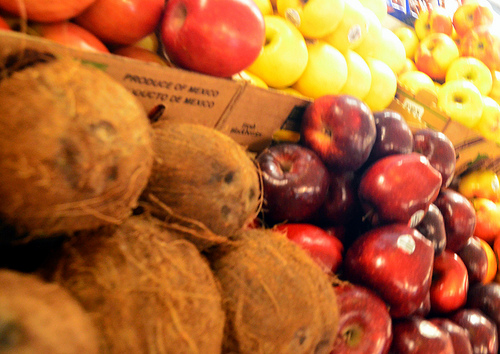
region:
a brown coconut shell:
[18, 65, 168, 240]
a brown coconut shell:
[147, 128, 261, 223]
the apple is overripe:
[257, 131, 340, 215]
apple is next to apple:
[252, 143, 330, 222]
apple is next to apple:
[307, 94, 377, 170]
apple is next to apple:
[270, 221, 340, 273]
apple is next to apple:
[311, 277, 387, 347]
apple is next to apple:
[345, 220, 432, 315]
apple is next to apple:
[395, 316, 450, 347]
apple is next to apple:
[429, 246, 468, 313]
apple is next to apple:
[439, 186, 477, 253]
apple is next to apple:
[370, 109, 414, 162]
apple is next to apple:
[415, 125, 454, 188]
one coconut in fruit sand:
[2, 55, 156, 239]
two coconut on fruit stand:
[3, 63, 259, 244]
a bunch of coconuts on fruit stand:
[10, 62, 341, 349]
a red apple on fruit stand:
[291, 93, 377, 168]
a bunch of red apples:
[236, 100, 496, 342]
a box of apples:
[233, 0, 408, 116]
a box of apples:
[0, 5, 265, 125]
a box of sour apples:
[385, 5, 496, 161]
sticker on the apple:
[336, 215, 434, 317]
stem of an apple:
[263, 140, 300, 181]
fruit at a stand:
[22, 7, 452, 296]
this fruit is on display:
[14, 9, 484, 279]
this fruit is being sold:
[191, 2, 491, 347]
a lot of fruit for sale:
[29, 7, 496, 236]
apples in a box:
[10, 5, 240, 85]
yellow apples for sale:
[266, 4, 405, 96]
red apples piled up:
[290, 119, 490, 336]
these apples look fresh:
[222, 19, 498, 305]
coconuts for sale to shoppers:
[27, 89, 309, 347]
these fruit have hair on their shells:
[27, 99, 296, 352]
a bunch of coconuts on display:
[6, 40, 339, 352]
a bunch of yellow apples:
[245, 2, 405, 111]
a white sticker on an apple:
[396, 232, 415, 255]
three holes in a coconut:
[218, 168, 257, 218]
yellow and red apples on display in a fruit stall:
[414, 0, 496, 81]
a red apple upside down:
[356, 148, 441, 222]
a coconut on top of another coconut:
[4, 54, 155, 239]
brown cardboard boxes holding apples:
[1, 28, 310, 168]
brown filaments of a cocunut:
[148, 194, 238, 246]